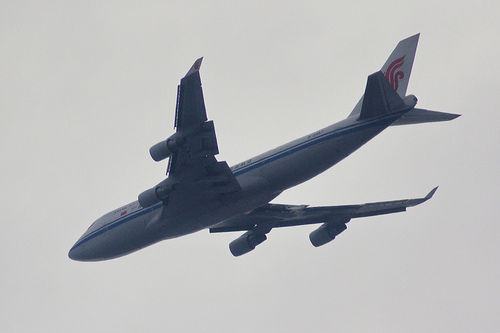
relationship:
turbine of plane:
[310, 222, 340, 250] [52, 35, 457, 276]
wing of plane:
[355, 26, 436, 106] [31, 17, 461, 289]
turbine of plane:
[150, 120, 215, 159] [67, 31, 463, 266]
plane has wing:
[67, 31, 463, 266] [355, 34, 435, 106]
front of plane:
[60, 212, 111, 273] [68, 21, 452, 276]